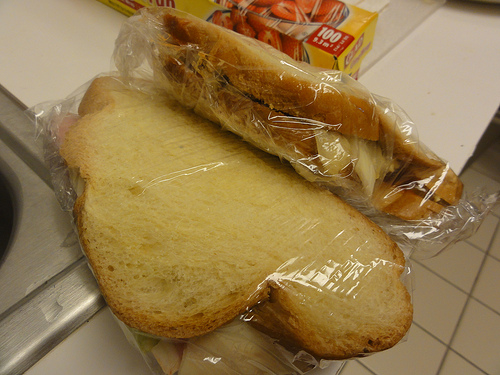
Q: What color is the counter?
A: White.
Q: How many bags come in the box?
A: 100.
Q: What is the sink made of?
A: Steel.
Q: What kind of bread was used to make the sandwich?
A: White bread.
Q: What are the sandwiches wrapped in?
A: Plastic.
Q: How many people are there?
A: None.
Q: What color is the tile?
A: White.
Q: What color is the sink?
A: Silver.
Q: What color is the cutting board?
A: White.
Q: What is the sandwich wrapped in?
A: Plastic.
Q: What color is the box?
A: Yellow.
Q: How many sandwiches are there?
A: Two.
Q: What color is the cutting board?
A: White.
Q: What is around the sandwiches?
A: Plastic wrap.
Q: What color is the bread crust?
A: Brown.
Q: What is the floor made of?
A: Tile.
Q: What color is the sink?
A: Silver.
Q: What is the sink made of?
A: Metal.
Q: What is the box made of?
A: Cardboard.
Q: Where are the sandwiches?
A: On the cutting board.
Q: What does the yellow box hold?
A: Plastic wrap.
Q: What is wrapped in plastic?
A: Sandwiches.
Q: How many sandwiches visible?
A: 2.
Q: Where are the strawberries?
A: On the yellow box.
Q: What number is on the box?
A: 100.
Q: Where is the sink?
A: Left of sandwiches.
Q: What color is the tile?
A: White.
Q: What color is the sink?
A: Silver.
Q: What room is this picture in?
A: Kitchen.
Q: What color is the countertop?
A: White.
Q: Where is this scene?
A: On a counter.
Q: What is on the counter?
A: A homemade lunch.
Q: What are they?
A: Sandwiches.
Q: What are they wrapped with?
A: Clear wrap.